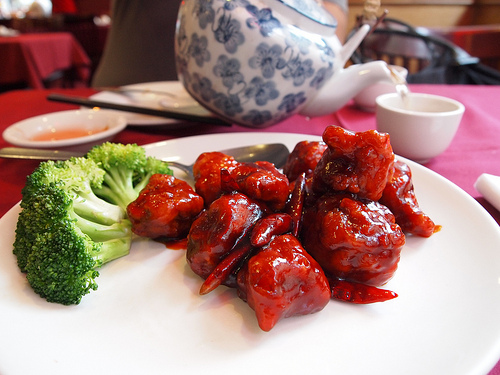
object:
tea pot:
[174, 0, 392, 131]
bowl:
[0, 108, 128, 154]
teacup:
[375, 92, 464, 163]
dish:
[1, 108, 127, 155]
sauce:
[26, 127, 110, 141]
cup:
[374, 91, 466, 165]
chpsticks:
[45, 94, 231, 125]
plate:
[300, 319, 349, 344]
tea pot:
[173, 2, 397, 120]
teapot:
[164, 0, 446, 132]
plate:
[175, 138, 211, 148]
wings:
[120, 122, 465, 331]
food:
[10, 124, 444, 332]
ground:
[441, 123, 461, 158]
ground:
[210, 127, 261, 134]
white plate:
[87, 78, 211, 125]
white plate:
[4, 109, 124, 146]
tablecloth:
[410, 74, 495, 168]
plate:
[119, 352, 473, 372]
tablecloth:
[0, 84, 500, 217]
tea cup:
[374, 84, 466, 164]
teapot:
[166, 9, 416, 131]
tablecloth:
[5, 30, 97, 84]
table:
[0, 81, 500, 226]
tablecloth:
[464, 95, 487, 173]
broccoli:
[12, 140, 175, 306]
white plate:
[0, 132, 500, 372]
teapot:
[172, 1, 405, 129]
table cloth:
[0, 30, 89, 89]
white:
[293, 61, 413, 125]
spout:
[302, 59, 397, 124]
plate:
[79, 79, 221, 126]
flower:
[212, 12, 246, 56]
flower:
[245, 42, 288, 80]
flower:
[279, 54, 315, 87]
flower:
[182, 32, 213, 69]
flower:
[211, 53, 245, 89]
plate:
[12, 324, 137, 374]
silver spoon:
[3, 141, 287, 167]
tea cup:
[364, 80, 472, 171]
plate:
[107, 264, 156, 292]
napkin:
[472, 172, 499, 214]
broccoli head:
[11, 155, 107, 305]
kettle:
[174, 0, 402, 129]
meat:
[235, 170, 393, 226]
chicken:
[125, 123, 441, 333]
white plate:
[434, 172, 497, 356]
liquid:
[49, 127, 69, 141]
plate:
[387, 326, 477, 366]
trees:
[22, 155, 138, 295]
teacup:
[369, 79, 464, 160]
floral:
[248, 42, 288, 82]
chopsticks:
[45, 94, 233, 128]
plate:
[0, 130, 499, 375]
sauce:
[182, 170, 410, 283]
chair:
[344, 15, 456, 85]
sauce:
[125, 122, 439, 331]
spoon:
[2, 143, 295, 173]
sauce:
[166, 233, 188, 251]